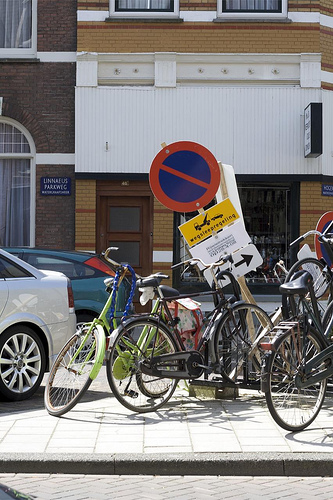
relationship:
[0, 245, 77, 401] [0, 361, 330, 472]
car near sidewalk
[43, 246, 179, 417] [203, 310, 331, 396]
bicycle on bike rack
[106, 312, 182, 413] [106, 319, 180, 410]
tire of tire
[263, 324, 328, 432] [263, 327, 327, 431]
tire of tire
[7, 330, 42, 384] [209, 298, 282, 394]
wheel of tire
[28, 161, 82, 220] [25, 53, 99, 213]
sign on wall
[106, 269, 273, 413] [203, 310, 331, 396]
bike on bike rack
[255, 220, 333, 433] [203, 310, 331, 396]
bike on bike rack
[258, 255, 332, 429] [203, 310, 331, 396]
bike on bike rack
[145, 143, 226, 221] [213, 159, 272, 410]
sign on post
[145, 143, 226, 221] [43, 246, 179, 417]
sign by bicycle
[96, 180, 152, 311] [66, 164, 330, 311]
door on building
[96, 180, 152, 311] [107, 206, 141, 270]
door has windows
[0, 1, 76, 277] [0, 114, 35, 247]
brick building has window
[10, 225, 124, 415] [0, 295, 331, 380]
car parked on street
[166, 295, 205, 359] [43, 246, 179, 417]
box behind bicycle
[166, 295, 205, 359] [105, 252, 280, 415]
box behind bike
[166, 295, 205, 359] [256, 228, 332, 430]
box behind bike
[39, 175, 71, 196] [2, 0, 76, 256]
sign on brick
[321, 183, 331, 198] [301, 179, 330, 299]
sign on brick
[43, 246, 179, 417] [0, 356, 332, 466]
bicycle are on pavement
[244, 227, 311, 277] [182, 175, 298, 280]
dog in reflection